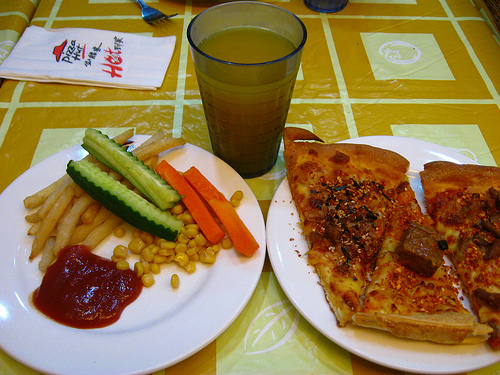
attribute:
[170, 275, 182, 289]
corn — small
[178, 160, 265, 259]
carrot — long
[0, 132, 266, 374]
plate — white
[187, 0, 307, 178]
glass — plastic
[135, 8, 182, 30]
fork — metal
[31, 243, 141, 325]
ketchup — red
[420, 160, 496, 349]
pizza — three pieces 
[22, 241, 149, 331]
ketchup — red and wet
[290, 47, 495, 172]
tablecloth — yellow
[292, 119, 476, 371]
pizza — slices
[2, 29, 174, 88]
napkin — white, paper, with pizza hut logo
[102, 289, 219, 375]
plate — white